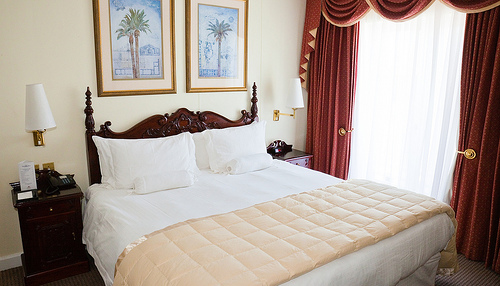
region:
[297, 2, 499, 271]
window curtains with white panel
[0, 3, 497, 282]
interior of bedroom with white wall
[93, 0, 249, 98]
two pictures in gold frame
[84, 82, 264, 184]
pillows in front of headboard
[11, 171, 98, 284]
night stand with telephone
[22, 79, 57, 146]
wall lamp with white shade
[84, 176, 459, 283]
folded quilt on foot of bed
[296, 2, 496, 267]
open red curtains with valance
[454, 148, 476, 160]
gold metal curtain tie back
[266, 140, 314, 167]
night stand next to bed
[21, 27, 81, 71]
this is the wall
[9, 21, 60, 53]
the wall is white in color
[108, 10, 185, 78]
this is a picture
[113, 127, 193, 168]
this is a pillow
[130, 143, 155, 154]
the pillow is white in color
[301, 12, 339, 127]
this is a curtain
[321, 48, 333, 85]
the curtain is red in color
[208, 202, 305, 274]
this is a blanket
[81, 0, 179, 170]
a picture of a palm tree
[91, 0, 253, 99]
two pictures of palm trees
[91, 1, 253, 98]
matted and framed pictures of palms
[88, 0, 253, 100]
matted and framed pictures of palm trees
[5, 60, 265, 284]
a night stand next to a bed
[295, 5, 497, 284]
fancy red curtains surrounding a window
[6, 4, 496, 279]
a bedroom with a two person bed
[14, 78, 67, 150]
a lamp attached to a wall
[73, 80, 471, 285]
a bed that has been made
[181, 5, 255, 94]
image on the wall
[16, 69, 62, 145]
light on the wall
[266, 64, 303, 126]
light on the wall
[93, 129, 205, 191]
pillow on the bed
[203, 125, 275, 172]
pillow on the bed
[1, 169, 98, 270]
desk next to bed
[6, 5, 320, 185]
wall with images on it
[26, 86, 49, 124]
shade on the light